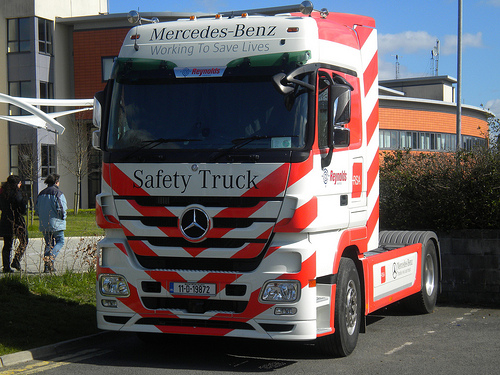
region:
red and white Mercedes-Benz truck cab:
[89, 7, 441, 359]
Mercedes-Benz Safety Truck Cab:
[92, 7, 442, 354]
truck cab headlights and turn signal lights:
[94, 270, 302, 315]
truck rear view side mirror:
[320, 80, 351, 166]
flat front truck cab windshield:
[101, 66, 308, 150]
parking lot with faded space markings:
[0, 306, 498, 373]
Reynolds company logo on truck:
[322, 166, 348, 187]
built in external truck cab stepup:
[315, 283, 332, 330]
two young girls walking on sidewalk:
[0, 171, 70, 274]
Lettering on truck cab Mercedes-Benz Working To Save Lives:
[145, 24, 275, 54]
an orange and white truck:
[87, 8, 471, 362]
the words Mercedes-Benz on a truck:
[147, 20, 283, 42]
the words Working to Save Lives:
[144, 39, 275, 56]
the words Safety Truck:
[126, 164, 263, 194]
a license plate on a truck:
[166, 277, 221, 299]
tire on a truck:
[330, 255, 366, 359]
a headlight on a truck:
[95, 270, 135, 301]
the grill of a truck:
[113, 187, 288, 277]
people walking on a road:
[5, 165, 73, 277]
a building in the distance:
[380, 64, 499, 173]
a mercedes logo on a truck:
[164, 203, 215, 245]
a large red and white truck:
[100, 9, 440, 356]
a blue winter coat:
[32, 185, 77, 236]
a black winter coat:
[0, 183, 32, 241]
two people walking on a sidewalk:
[0, 166, 88, 275]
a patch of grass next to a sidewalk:
[4, 275, 106, 345]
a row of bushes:
[389, 157, 495, 225]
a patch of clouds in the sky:
[380, 25, 475, 86]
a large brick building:
[73, 22, 498, 224]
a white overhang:
[0, 86, 82, 148]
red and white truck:
[95, 28, 382, 373]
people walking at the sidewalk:
[2, 160, 101, 287]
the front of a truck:
[81, 2, 385, 362]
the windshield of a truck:
[118, 85, 292, 156]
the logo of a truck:
[125, 162, 256, 212]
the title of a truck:
[142, 21, 292, 63]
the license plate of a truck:
[164, 278, 215, 309]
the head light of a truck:
[257, 268, 308, 315]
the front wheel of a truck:
[314, 256, 375, 344]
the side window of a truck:
[317, 81, 359, 148]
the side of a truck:
[364, 233, 429, 308]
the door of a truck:
[338, 161, 372, 226]